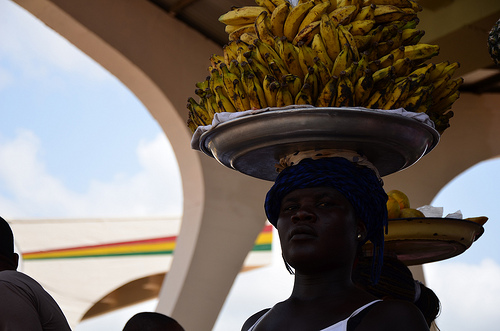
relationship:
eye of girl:
[318, 195, 335, 209] [235, 155, 442, 326]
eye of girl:
[276, 201, 296, 214] [235, 155, 442, 326]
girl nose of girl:
[291, 212, 318, 221] [237, 146, 438, 330]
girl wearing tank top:
[237, 146, 438, 330] [243, 288, 393, 329]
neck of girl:
[278, 264, 364, 296] [176, 108, 418, 328]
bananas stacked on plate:
[185, 0, 464, 130] [198, 103, 440, 182]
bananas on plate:
[185, 0, 465, 131] [198, 103, 440, 182]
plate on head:
[198, 103, 440, 182] [262, 162, 381, 272]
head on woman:
[262, 162, 381, 272] [248, 158, 435, 327]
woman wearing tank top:
[248, 158, 435, 327] [238, 292, 370, 320]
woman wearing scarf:
[248, 158, 435, 327] [257, 157, 392, 191]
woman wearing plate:
[248, 158, 435, 327] [170, 91, 440, 160]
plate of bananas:
[170, 91, 440, 160] [159, 1, 465, 116]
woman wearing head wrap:
[248, 158, 435, 327] [258, 163, 386, 201]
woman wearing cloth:
[248, 158, 435, 327] [262, 154, 394, 289]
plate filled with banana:
[198, 103, 440, 182] [223, 71, 235, 86]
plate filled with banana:
[198, 103, 440, 182] [218, 93, 232, 110]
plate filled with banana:
[198, 103, 440, 182] [309, 33, 324, 60]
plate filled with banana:
[198, 103, 440, 182] [331, 41, 348, 75]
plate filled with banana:
[198, 103, 440, 182] [253, 8, 277, 43]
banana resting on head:
[223, 71, 235, 86] [258, 162, 381, 272]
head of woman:
[258, 162, 381, 272] [239, 158, 436, 331]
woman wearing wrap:
[239, 158, 436, 331] [260, 154, 391, 228]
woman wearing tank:
[239, 158, 436, 331] [234, 282, 376, 328]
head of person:
[262, 162, 381, 272] [240, 147, 429, 329]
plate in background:
[383, 212, 475, 260] [118, 152, 484, 286]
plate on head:
[198, 103, 440, 182] [249, 162, 393, 272]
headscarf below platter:
[262, 159, 422, 219] [191, 71, 499, 172]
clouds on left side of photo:
[11, 117, 203, 229] [4, 6, 484, 301]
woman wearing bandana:
[248, 158, 435, 327] [240, 161, 402, 217]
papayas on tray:
[378, 179, 432, 216] [192, 111, 442, 186]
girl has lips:
[237, 146, 438, 330] [282, 220, 321, 247]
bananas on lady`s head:
[185, 0, 464, 130] [263, 154, 389, 277]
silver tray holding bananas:
[197, 110, 442, 170] [185, 0, 464, 130]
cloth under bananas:
[260, 151, 390, 269] [185, 0, 464, 130]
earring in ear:
[356, 231, 361, 237] [356, 218, 366, 243]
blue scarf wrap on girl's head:
[264, 153, 424, 222] [261, 159, 388, 279]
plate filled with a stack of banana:
[198, 103, 440, 182] [254, 9, 274, 45]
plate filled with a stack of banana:
[198, 103, 440, 182] [269, 1, 289, 38]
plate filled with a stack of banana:
[198, 103, 440, 182] [283, 0, 318, 42]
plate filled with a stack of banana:
[198, 103, 440, 182] [297, 0, 334, 32]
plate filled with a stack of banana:
[198, 103, 440, 182] [218, 5, 271, 26]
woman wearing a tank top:
[248, 158, 435, 327] [230, 292, 385, 329]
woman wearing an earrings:
[239, 158, 436, 331] [357, 231, 364, 238]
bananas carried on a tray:
[185, 0, 464, 130] [194, 104, 440, 181]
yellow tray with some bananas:
[361, 215, 485, 264] [185, 0, 464, 130]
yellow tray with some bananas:
[361, 215, 485, 264] [387, 187, 426, 219]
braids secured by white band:
[360, 254, 445, 320] [406, 270, 426, 307]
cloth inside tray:
[190, 104, 432, 151] [201, 103, 415, 173]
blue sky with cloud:
[32, 78, 131, 150] [9, 109, 189, 215]